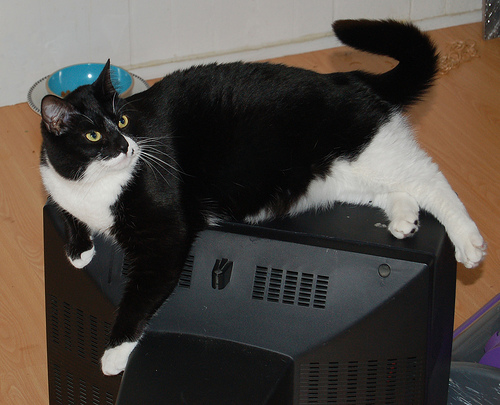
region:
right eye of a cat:
[85, 127, 101, 140]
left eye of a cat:
[122, 105, 131, 131]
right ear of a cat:
[39, 92, 58, 130]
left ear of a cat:
[106, 65, 118, 93]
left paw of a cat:
[456, 220, 482, 272]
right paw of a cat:
[393, 208, 420, 236]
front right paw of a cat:
[63, 236, 93, 263]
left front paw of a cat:
[102, 345, 122, 369]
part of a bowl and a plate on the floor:
[113, 62, 140, 91]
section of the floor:
[469, 47, 499, 199]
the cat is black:
[58, 88, 498, 245]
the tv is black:
[41, 219, 442, 403]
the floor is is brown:
[455, 125, 490, 182]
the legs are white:
[381, 166, 473, 263]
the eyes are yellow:
[83, 119, 140, 143]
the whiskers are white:
[135, 131, 178, 186]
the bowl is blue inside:
[43, 68, 142, 90]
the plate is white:
[32, 61, 163, 99]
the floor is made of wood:
[6, 188, 33, 360]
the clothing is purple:
[472, 329, 497, 351]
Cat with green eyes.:
[53, 105, 182, 154]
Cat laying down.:
[39, 46, 416, 241]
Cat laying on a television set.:
[38, 10, 486, 356]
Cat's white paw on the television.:
[66, 271, 183, 371]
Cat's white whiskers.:
[26, 65, 221, 215]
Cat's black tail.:
[317, 12, 477, 117]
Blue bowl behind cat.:
[41, 46, 202, 167]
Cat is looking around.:
[30, 90, 115, 150]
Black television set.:
[37, 185, 482, 346]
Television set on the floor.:
[8, 183, 41, 234]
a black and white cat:
[41, 18, 486, 370]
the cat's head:
[36, 58, 141, 168]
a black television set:
[29, 200, 461, 404]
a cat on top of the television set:
[36, 16, 482, 403]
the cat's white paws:
[385, 214, 498, 271]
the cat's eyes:
[85, 115, 129, 141]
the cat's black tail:
[335, 20, 441, 97]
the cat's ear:
[39, 93, 80, 137]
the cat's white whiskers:
[136, 133, 188, 186]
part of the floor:
[439, 103, 498, 165]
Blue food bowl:
[48, 53, 133, 119]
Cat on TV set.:
[20, 46, 395, 346]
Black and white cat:
[30, 60, 175, 270]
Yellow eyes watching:
[30, 70, 155, 150]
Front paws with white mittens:
[30, 80, 155, 377]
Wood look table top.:
[5, 100, 42, 290]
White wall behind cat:
[102, 12, 323, 87]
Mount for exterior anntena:
[167, 212, 268, 324]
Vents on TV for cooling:
[209, 244, 349, 346]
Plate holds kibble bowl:
[12, 49, 74, 128]